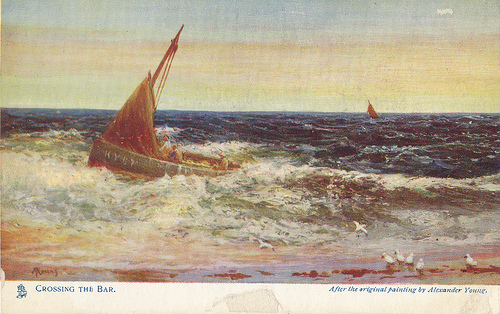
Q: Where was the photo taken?
A: It was taken at the ocean.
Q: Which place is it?
A: It is an ocean.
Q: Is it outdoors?
A: Yes, it is outdoors.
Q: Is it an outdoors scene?
A: Yes, it is outdoors.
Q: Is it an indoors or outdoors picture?
A: It is outdoors.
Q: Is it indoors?
A: No, it is outdoors.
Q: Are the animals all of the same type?
A: Yes, all the animals are birds.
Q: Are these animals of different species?
A: No, all the animals are birds.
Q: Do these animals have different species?
A: No, all the animals are birds.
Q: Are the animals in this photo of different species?
A: No, all the animals are birds.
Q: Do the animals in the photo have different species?
A: No, all the animals are birds.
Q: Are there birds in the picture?
A: Yes, there is a bird.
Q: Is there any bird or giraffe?
A: Yes, there is a bird.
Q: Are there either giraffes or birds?
A: Yes, there is a bird.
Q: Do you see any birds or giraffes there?
A: Yes, there is a bird.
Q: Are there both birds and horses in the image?
A: No, there is a bird but no horses.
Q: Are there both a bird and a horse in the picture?
A: No, there is a bird but no horses.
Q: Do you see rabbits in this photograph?
A: No, there are no rabbits.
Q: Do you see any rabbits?
A: No, there are no rabbits.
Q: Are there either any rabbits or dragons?
A: No, there are no rabbits or dragons.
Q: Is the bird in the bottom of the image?
A: Yes, the bird is in the bottom of the image.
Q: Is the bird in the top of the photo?
A: No, the bird is in the bottom of the image.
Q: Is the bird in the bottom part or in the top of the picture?
A: The bird is in the bottom of the image.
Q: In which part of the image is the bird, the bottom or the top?
A: The bird is in the bottom of the image.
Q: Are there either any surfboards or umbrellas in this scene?
A: No, there are no surfboards or umbrellas.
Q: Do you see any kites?
A: No, there are no kites.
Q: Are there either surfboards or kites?
A: No, there are no kites or surfboards.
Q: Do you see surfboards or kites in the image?
A: No, there are no kites or surfboards.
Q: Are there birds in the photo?
A: Yes, there are birds.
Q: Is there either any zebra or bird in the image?
A: Yes, there are birds.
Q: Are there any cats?
A: No, there are no cats.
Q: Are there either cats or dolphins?
A: No, there are no cats or dolphins.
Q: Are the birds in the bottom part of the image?
A: Yes, the birds are in the bottom of the image.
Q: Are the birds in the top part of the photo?
A: No, the birds are in the bottom of the image.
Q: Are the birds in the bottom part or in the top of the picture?
A: The birds are in the bottom of the image.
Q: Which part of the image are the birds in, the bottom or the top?
A: The birds are in the bottom of the image.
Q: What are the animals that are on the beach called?
A: The animals are birds.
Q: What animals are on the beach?
A: The animals are birds.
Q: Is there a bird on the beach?
A: Yes, there are birds on the beach.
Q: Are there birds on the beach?
A: Yes, there are birds on the beach.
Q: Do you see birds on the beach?
A: Yes, there are birds on the beach.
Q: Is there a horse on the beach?
A: No, there are birds on the beach.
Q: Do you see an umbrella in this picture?
A: No, there are no umbrellas.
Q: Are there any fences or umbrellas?
A: No, there are no umbrellas or fences.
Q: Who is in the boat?
A: The people are in the boat.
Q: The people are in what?
A: The people are in the boat.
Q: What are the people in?
A: The people are in the boat.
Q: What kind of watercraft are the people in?
A: The people are in the boat.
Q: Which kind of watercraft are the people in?
A: The people are in the boat.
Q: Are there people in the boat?
A: Yes, there are people in the boat.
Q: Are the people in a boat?
A: Yes, the people are in a boat.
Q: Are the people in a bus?
A: No, the people are in a boat.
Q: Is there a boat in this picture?
A: Yes, there is a boat.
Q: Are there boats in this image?
A: Yes, there is a boat.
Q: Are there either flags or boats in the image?
A: Yes, there is a boat.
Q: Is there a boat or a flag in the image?
A: Yes, there is a boat.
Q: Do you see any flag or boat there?
A: Yes, there is a boat.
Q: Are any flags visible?
A: No, there are no flags.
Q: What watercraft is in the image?
A: The watercraft is a boat.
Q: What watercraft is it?
A: The watercraft is a boat.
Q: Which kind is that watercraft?
A: This is a boat.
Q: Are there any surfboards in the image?
A: No, there are no surfboards.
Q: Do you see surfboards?
A: No, there are no surfboards.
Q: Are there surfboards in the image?
A: No, there are no surfboards.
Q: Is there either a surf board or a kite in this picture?
A: No, there are no surfboards or kites.